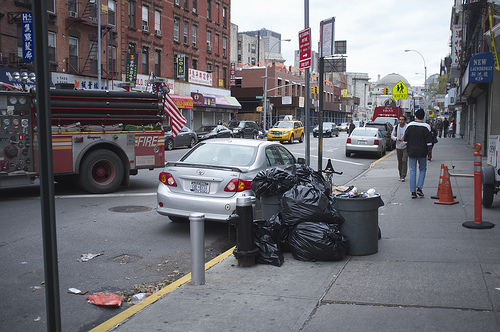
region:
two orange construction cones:
[428, 158, 461, 220]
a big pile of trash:
[247, 163, 382, 273]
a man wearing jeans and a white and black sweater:
[395, 98, 446, 207]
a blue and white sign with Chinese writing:
[6, 5, 43, 65]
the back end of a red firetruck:
[1, 80, 176, 195]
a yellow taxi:
[258, 114, 308, 150]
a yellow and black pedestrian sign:
[388, 74, 407, 149]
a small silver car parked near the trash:
[135, 129, 312, 234]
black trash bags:
[285, 175, 344, 260]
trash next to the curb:
[67, 279, 167, 330]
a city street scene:
[10, 3, 485, 323]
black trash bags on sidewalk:
[227, 160, 332, 295]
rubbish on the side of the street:
[57, 238, 182, 318]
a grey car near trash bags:
[151, 125, 321, 260]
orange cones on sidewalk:
[425, 145, 466, 268]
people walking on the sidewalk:
[385, 105, 448, 217]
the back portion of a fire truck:
[0, 68, 183, 193]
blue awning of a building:
[451, 45, 496, 166]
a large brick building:
[0, 32, 241, 142]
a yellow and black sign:
[381, 70, 415, 133]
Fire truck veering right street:
[2, 60, 165, 216]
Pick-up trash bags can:
[262, 163, 394, 262]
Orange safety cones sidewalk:
[432, 146, 487, 243]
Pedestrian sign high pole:
[379, 78, 416, 114]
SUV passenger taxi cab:
[267, 115, 314, 145]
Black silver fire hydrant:
[220, 190, 269, 272]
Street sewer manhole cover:
[97, 195, 159, 235]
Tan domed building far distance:
[373, 71, 418, 91]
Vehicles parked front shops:
[175, 120, 262, 139]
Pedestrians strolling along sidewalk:
[392, 112, 437, 203]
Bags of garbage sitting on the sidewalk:
[223, 158, 400, 275]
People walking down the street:
[385, 90, 463, 202]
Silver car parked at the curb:
[154, 111, 318, 221]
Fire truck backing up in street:
[1, 62, 178, 194]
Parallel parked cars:
[174, 112, 304, 144]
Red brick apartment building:
[140, 13, 240, 117]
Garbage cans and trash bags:
[246, 160, 391, 261]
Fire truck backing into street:
[6, 58, 176, 206]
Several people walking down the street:
[371, 9, 498, 293]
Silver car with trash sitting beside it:
[149, 120, 398, 306]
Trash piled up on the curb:
[266, 170, 346, 264]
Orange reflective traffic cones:
[431, 160, 457, 206]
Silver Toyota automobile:
[156, 154, 239, 217]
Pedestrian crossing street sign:
[385, 80, 412, 102]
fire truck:
[11, 88, 153, 173]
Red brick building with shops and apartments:
[160, 0, 235, 127]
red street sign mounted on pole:
[290, 23, 322, 75]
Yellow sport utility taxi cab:
[266, 115, 306, 145]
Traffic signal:
[304, 77, 324, 100]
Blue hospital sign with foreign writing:
[16, 9, 38, 61]